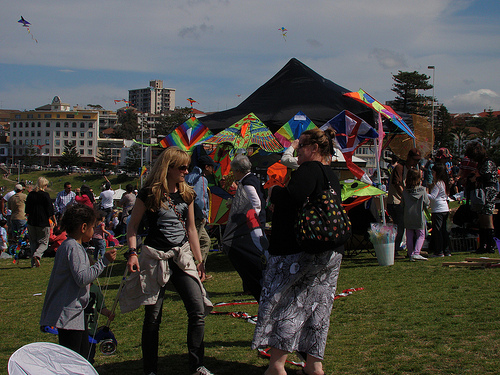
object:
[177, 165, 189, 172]
sunglasses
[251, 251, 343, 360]
skirt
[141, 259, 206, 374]
pants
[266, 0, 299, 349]
tree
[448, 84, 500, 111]
cloud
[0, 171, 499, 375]
grass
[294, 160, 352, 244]
purse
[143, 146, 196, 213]
hair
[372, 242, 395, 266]
bucket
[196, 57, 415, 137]
tent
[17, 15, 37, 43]
kite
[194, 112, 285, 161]
kites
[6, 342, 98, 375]
kite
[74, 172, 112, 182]
shadows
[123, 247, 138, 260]
bracelets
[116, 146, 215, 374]
woman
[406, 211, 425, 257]
pants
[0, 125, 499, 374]
people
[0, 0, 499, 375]
area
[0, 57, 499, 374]
festival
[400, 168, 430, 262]
children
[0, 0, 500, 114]
weather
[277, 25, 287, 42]
kite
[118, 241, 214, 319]
jacket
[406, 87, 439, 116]
green leaves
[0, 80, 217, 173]
building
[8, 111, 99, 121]
yellow top floor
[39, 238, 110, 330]
shirt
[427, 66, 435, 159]
lamp post